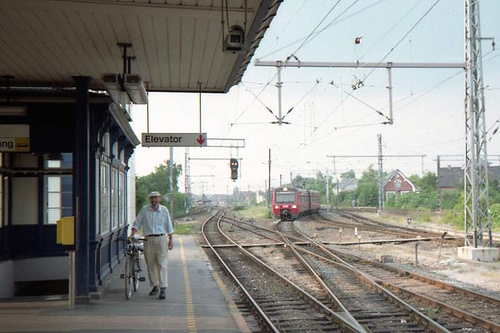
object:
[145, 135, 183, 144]
elevator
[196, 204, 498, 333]
tracks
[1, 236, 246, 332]
platform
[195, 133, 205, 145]
arrow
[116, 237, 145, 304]
bicycle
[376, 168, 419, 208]
house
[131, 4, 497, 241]
background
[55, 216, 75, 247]
box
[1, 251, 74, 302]
entrance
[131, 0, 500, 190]
sky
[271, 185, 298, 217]
front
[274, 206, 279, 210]
headlight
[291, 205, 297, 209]
headlight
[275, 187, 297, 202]
window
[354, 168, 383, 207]
tree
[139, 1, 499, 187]
distance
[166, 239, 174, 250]
hand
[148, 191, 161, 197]
cap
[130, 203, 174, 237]
shirt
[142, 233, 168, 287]
pants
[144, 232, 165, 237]
belt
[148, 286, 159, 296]
shoes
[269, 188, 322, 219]
engine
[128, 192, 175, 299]
he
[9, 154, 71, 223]
windows